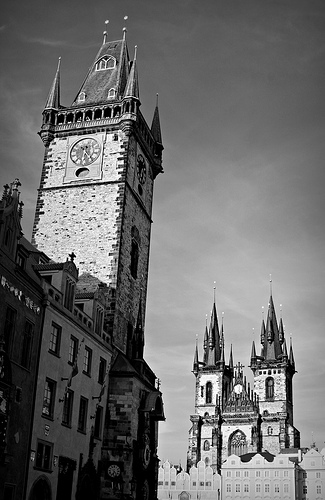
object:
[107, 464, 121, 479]
clock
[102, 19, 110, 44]
spiers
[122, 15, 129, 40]
spiers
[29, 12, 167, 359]
clock tower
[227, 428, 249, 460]
door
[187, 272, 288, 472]
front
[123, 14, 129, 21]
light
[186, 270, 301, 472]
cathedral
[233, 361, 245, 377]
cross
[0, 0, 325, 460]
sky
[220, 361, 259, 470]
middle tower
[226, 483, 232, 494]
windows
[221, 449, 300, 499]
building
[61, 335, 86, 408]
flag pole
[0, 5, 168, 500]
cathedral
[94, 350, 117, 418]
flag pole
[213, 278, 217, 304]
spire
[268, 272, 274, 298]
spire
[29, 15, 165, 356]
building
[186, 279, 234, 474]
tower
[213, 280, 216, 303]
antenna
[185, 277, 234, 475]
building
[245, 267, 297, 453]
tower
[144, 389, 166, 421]
overhanging eve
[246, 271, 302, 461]
right towerl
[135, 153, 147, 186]
clock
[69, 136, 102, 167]
clock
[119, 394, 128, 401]
bricks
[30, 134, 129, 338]
brick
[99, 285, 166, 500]
building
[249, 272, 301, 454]
building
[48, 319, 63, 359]
window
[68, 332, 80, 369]
window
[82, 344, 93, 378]
window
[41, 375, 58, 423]
window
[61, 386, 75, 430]
window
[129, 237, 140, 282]
window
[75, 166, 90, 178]
window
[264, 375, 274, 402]
window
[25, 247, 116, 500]
building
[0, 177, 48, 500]
building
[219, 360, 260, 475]
tower